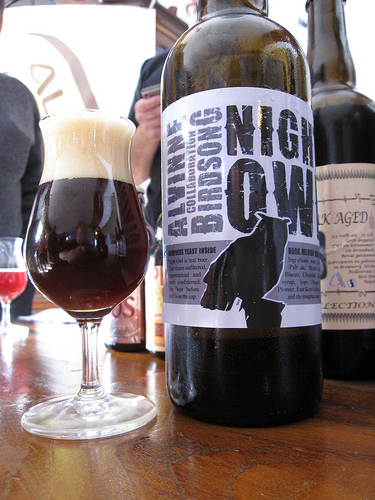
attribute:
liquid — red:
[1, 266, 27, 304]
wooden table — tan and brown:
[2, 320, 373, 498]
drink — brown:
[20, 86, 181, 292]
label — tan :
[312, 161, 374, 330]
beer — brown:
[23, 177, 151, 311]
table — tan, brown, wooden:
[0, 321, 372, 498]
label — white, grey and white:
[157, 90, 326, 332]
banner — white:
[1, 3, 162, 123]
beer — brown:
[31, 175, 148, 314]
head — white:
[53, 115, 119, 187]